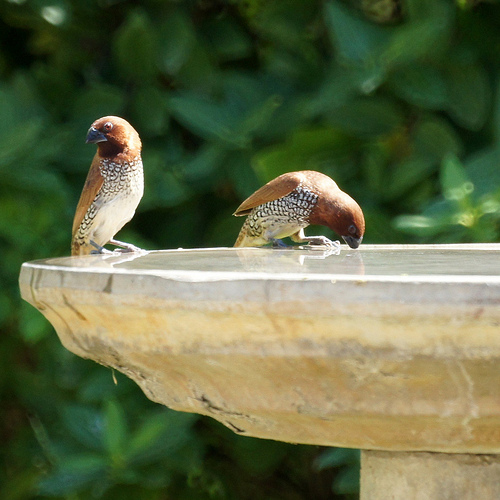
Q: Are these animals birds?
A: Yes, all the animals are birds.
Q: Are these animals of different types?
A: No, all the animals are birds.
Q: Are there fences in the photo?
A: No, there are no fences.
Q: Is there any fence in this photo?
A: No, there are no fences.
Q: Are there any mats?
A: No, there are no mats.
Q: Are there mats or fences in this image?
A: No, there are no mats or fences.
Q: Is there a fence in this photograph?
A: No, there are no fences.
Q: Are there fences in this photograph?
A: No, there are no fences.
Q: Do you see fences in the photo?
A: No, there are no fences.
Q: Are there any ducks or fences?
A: No, there are no fences or ducks.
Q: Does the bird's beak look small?
A: Yes, the beak is small.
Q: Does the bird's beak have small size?
A: Yes, the beak is small.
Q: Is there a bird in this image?
A: Yes, there is a bird.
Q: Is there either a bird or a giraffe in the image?
A: Yes, there is a bird.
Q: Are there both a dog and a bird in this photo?
A: No, there is a bird but no dogs.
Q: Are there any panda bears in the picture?
A: No, there are no panda bears.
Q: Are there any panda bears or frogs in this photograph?
A: No, there are no panda bears or frogs.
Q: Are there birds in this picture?
A: Yes, there is a bird.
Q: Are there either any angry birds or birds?
A: Yes, there is a bird.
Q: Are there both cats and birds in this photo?
A: No, there is a bird but no cats.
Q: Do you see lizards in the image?
A: No, there are no lizards.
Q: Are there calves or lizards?
A: No, there are no lizards or calves.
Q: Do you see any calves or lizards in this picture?
A: No, there are no lizards or calves.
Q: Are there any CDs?
A: No, there are no cds.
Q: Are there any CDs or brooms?
A: No, there are no CDs or brooms.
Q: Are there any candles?
A: No, there are no candles.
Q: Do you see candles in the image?
A: No, there are no candles.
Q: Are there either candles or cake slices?
A: No, there are no candles or cake slices.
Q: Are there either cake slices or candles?
A: No, there are no candles or cake slices.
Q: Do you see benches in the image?
A: No, there are no benches.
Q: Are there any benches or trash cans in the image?
A: No, there are no benches or trash cans.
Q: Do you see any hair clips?
A: No, there are no hair clips.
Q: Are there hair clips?
A: No, there are no hair clips.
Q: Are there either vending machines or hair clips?
A: No, there are no hair clips or vending machines.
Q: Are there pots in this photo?
A: No, there are no pots.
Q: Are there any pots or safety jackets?
A: No, there are no pots or safety jackets.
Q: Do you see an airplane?
A: No, there are no airplanes.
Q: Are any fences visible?
A: No, there are no fences.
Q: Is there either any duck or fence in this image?
A: No, there are no fences or ducks.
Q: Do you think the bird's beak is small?
A: Yes, the beak is small.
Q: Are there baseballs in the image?
A: No, there are no baseballs.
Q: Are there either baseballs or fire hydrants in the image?
A: No, there are no baseballs or fire hydrants.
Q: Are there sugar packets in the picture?
A: No, there are no sugar packets.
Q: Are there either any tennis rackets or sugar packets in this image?
A: No, there are no sugar packets or tennis rackets.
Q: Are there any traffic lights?
A: No, there are no traffic lights.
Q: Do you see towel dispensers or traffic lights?
A: No, there are no traffic lights or towel dispensers.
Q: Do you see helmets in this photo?
A: No, there are no helmets.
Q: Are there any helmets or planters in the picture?
A: No, there are no helmets or planters.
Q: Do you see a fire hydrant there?
A: No, there are no fire hydrants.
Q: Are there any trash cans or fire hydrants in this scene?
A: No, there are no fire hydrants or trash cans.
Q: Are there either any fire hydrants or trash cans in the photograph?
A: No, there are no fire hydrants or trash cans.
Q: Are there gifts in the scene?
A: No, there are no gifts.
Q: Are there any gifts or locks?
A: No, there are no gifts or locks.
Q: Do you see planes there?
A: No, there are no planes.